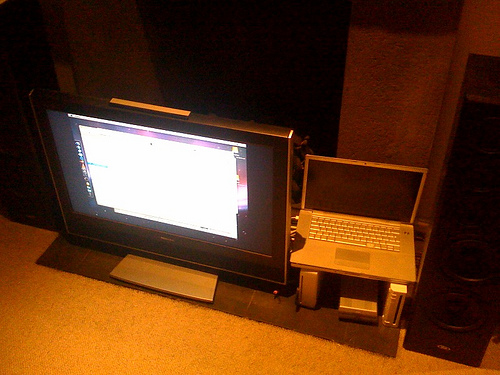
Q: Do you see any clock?
A: No, there are no clocks.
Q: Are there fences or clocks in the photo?
A: No, there are no clocks or fences.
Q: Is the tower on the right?
A: Yes, the tower is on the right of the image.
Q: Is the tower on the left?
A: No, the tower is on the right of the image.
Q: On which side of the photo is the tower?
A: The tower is on the right of the image.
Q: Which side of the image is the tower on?
A: The tower is on the right of the image.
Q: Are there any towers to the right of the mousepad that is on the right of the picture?
A: Yes, there is a tower to the right of the mousepad.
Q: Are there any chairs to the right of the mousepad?
A: No, there is a tower to the right of the mousepad.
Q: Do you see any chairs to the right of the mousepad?
A: No, there is a tower to the right of the mousepad.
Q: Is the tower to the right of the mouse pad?
A: Yes, the tower is to the right of the mouse pad.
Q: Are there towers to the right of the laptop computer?
A: Yes, there is a tower to the right of the laptop computer.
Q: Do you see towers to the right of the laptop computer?
A: Yes, there is a tower to the right of the laptop computer.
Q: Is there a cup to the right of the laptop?
A: No, there is a tower to the right of the laptop.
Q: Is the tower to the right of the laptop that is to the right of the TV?
A: Yes, the tower is to the right of the laptop.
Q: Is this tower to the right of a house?
A: No, the tower is to the right of the laptop.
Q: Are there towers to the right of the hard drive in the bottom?
A: Yes, there is a tower to the right of the hard drive.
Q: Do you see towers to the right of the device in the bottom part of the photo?
A: Yes, there is a tower to the right of the hard drive.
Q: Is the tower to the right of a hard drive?
A: Yes, the tower is to the right of a hard drive.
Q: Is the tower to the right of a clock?
A: No, the tower is to the right of a hard drive.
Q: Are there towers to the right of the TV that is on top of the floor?
A: Yes, there is a tower to the right of the TV.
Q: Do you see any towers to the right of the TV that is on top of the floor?
A: Yes, there is a tower to the right of the TV.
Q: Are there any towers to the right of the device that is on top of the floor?
A: Yes, there is a tower to the right of the TV.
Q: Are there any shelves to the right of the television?
A: No, there is a tower to the right of the television.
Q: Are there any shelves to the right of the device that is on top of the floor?
A: No, there is a tower to the right of the television.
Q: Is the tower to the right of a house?
A: No, the tower is to the right of the television.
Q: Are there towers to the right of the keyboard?
A: Yes, there is a tower to the right of the keyboard.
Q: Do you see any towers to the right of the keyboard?
A: Yes, there is a tower to the right of the keyboard.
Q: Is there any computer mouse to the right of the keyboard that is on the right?
A: No, there is a tower to the right of the keyboard.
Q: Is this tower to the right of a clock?
A: No, the tower is to the right of the keyboard.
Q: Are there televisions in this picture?
A: Yes, there is a television.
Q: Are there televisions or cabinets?
A: Yes, there is a television.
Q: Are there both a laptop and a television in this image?
A: Yes, there are both a television and a laptop.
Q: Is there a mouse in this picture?
A: No, there are no computer mice.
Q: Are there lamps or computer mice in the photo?
A: No, there are no computer mice or lamps.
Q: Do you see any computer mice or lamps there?
A: No, there are no computer mice or lamps.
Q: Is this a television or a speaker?
A: This is a television.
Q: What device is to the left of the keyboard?
A: The device is a television.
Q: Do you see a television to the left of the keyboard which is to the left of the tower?
A: Yes, there is a television to the left of the keyboard.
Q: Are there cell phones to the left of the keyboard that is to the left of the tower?
A: No, there is a television to the left of the keyboard.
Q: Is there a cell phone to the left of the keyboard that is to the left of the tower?
A: No, there is a television to the left of the keyboard.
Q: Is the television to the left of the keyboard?
A: Yes, the television is to the left of the keyboard.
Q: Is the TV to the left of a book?
A: No, the TV is to the left of the keyboard.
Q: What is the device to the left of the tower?
A: The device is a television.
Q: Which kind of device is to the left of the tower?
A: The device is a television.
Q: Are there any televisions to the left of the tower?
A: Yes, there is a television to the left of the tower.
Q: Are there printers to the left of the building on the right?
A: No, there is a television to the left of the tower.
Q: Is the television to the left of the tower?
A: Yes, the television is to the left of the tower.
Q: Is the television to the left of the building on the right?
A: Yes, the television is to the left of the tower.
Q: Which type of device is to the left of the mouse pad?
A: The device is a television.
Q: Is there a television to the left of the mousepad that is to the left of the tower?
A: Yes, there is a television to the left of the mousepad.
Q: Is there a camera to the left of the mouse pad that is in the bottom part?
A: No, there is a television to the left of the mousepad.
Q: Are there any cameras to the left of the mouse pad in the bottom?
A: No, there is a television to the left of the mousepad.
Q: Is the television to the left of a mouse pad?
A: Yes, the television is to the left of a mouse pad.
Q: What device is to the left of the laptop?
A: The device is a television.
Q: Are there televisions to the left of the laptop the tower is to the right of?
A: Yes, there is a television to the left of the laptop computer.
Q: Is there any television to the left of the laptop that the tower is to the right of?
A: Yes, there is a television to the left of the laptop computer.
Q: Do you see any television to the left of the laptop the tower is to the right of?
A: Yes, there is a television to the left of the laptop computer.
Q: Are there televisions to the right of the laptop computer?
A: No, the television is to the left of the laptop computer.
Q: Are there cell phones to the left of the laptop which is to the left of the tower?
A: No, there is a television to the left of the laptop.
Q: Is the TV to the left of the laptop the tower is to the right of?
A: Yes, the TV is to the left of the laptop.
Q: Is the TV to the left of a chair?
A: No, the TV is to the left of the laptop.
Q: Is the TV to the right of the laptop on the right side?
A: No, the TV is to the left of the laptop.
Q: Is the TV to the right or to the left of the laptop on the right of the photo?
A: The TV is to the left of the laptop.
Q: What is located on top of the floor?
A: The television is on top of the floor.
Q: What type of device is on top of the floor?
A: The device is a television.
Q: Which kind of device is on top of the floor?
A: The device is a television.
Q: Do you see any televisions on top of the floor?
A: Yes, there is a television on top of the floor.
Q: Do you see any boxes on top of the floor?
A: No, there is a television on top of the floor.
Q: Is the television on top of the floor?
A: Yes, the television is on top of the floor.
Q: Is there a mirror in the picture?
A: No, there are no mirrors.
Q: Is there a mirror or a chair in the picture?
A: No, there are no mirrors or chairs.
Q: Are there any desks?
A: No, there are no desks.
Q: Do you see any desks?
A: No, there are no desks.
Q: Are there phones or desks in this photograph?
A: No, there are no desks or phones.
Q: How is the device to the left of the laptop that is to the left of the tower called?
A: The device is a screen.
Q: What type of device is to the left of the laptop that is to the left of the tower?
A: The device is a screen.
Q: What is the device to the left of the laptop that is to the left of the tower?
A: The device is a screen.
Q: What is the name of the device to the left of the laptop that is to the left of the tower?
A: The device is a screen.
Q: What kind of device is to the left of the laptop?
A: The device is a screen.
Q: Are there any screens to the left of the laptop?
A: Yes, there is a screen to the left of the laptop.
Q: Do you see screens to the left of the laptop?
A: Yes, there is a screen to the left of the laptop.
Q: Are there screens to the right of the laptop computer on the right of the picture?
A: No, the screen is to the left of the laptop.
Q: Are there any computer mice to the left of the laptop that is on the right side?
A: No, there is a screen to the left of the laptop.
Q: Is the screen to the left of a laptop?
A: Yes, the screen is to the left of a laptop.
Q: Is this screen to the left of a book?
A: No, the screen is to the left of a laptop.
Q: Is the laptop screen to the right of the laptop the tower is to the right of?
A: No, the screen is to the left of the laptop computer.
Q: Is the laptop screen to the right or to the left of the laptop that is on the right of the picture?
A: The screen is to the left of the laptop.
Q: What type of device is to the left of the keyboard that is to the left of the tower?
A: The device is a screen.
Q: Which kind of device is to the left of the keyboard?
A: The device is a screen.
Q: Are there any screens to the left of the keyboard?
A: Yes, there is a screen to the left of the keyboard.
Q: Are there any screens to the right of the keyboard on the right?
A: No, the screen is to the left of the keyboard.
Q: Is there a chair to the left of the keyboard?
A: No, there is a screen to the left of the keyboard.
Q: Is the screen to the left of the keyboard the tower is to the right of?
A: Yes, the screen is to the left of the keyboard.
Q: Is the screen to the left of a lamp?
A: No, the screen is to the left of the keyboard.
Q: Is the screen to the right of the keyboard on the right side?
A: No, the screen is to the left of the keyboard.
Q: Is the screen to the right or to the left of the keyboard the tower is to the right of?
A: The screen is to the left of the keyboard.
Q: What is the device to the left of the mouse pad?
A: The device is a screen.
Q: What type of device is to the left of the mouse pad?
A: The device is a screen.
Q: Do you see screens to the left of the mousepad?
A: Yes, there is a screen to the left of the mousepad.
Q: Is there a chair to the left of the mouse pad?
A: No, there is a screen to the left of the mouse pad.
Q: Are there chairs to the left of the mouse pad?
A: No, there is a screen to the left of the mouse pad.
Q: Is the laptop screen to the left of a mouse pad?
A: Yes, the screen is to the left of a mouse pad.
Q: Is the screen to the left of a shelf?
A: No, the screen is to the left of a mouse pad.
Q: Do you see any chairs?
A: No, there are no chairs.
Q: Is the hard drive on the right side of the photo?
A: Yes, the hard drive is on the right of the image.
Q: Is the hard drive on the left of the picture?
A: No, the hard drive is on the right of the image.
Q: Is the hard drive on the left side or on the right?
A: The hard drive is on the right of the image.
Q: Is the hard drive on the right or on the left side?
A: The hard drive is on the right of the image.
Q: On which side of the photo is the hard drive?
A: The hard drive is on the right of the image.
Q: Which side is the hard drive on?
A: The hard drive is on the right of the image.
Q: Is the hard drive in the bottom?
A: Yes, the hard drive is in the bottom of the image.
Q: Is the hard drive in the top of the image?
A: No, the hard drive is in the bottom of the image.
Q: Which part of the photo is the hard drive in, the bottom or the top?
A: The hard drive is in the bottom of the image.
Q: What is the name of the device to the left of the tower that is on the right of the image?
A: The device is a hard drive.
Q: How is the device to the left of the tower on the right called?
A: The device is a hard drive.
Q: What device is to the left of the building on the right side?
A: The device is a hard drive.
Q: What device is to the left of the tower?
A: The device is a hard drive.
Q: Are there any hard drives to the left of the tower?
A: Yes, there is a hard drive to the left of the tower.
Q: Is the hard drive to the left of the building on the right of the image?
A: Yes, the hard drive is to the left of the tower.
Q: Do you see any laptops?
A: Yes, there is a laptop.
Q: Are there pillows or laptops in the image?
A: Yes, there is a laptop.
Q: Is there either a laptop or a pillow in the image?
A: Yes, there is a laptop.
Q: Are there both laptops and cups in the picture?
A: No, there is a laptop but no cups.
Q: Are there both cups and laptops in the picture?
A: No, there is a laptop but no cups.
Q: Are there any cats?
A: No, there are no cats.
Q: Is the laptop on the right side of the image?
A: Yes, the laptop is on the right of the image.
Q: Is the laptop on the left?
A: No, the laptop is on the right of the image.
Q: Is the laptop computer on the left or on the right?
A: The laptop computer is on the right of the image.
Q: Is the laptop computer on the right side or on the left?
A: The laptop computer is on the right of the image.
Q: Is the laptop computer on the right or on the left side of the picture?
A: The laptop computer is on the right of the image.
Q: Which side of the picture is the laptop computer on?
A: The laptop computer is on the right of the image.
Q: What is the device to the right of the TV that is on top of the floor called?
A: The device is a laptop.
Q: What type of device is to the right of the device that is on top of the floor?
A: The device is a laptop.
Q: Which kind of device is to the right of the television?
A: The device is a laptop.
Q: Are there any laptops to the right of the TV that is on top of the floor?
A: Yes, there is a laptop to the right of the TV.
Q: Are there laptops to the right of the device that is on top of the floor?
A: Yes, there is a laptop to the right of the TV.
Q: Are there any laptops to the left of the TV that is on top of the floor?
A: No, the laptop is to the right of the TV.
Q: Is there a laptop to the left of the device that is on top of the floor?
A: No, the laptop is to the right of the TV.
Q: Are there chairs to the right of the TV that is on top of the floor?
A: No, there is a laptop to the right of the television.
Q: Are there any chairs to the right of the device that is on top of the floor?
A: No, there is a laptop to the right of the television.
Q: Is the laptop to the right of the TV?
A: Yes, the laptop is to the right of the TV.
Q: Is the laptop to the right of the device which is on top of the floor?
A: Yes, the laptop is to the right of the TV.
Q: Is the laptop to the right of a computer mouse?
A: No, the laptop is to the right of the TV.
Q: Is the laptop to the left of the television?
A: No, the laptop is to the right of the television.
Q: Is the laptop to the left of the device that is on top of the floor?
A: No, the laptop is to the right of the television.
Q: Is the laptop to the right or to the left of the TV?
A: The laptop is to the right of the TV.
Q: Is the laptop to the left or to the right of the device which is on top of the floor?
A: The laptop is to the right of the TV.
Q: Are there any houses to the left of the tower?
A: No, there is a laptop to the left of the tower.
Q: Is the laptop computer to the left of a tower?
A: Yes, the laptop computer is to the left of a tower.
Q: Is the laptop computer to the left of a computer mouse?
A: No, the laptop computer is to the left of a tower.